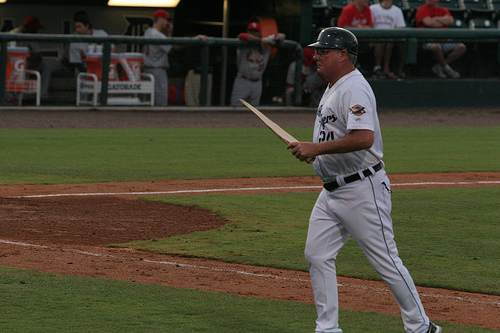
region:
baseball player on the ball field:
[8, 6, 485, 331]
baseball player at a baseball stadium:
[5, 5, 499, 317]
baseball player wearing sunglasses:
[237, 20, 444, 308]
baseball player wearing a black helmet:
[247, 13, 456, 325]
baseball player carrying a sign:
[226, 21, 450, 331]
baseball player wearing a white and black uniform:
[217, 15, 429, 327]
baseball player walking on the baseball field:
[217, 25, 444, 325]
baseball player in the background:
[3, 8, 485, 101]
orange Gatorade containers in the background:
[9, 9, 205, 125]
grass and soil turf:
[13, 114, 488, 325]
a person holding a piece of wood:
[243, 114, 396, 171]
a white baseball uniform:
[314, 67, 427, 331]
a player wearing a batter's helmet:
[305, 22, 362, 53]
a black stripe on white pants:
[362, 187, 389, 247]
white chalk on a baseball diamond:
[88, 185, 122, 200]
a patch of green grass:
[144, 192, 246, 212]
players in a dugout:
[136, 7, 277, 85]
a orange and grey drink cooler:
[6, 44, 31, 92]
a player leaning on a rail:
[231, 21, 288, 76]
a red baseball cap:
[150, 6, 175, 21]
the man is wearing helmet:
[301, 26, 374, 61]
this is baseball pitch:
[4, 131, 246, 328]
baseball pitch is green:
[3, 282, 182, 328]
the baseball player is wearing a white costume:
[317, 71, 409, 331]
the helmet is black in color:
[313, 24, 356, 49]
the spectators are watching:
[0, 15, 454, 92]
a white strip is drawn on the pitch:
[16, 186, 314, 196]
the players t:
[299, 178, 394, 332]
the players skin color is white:
[346, 133, 365, 142]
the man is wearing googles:
[313, 48, 330, 54]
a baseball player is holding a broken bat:
[229, 28, 466, 331]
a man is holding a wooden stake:
[237, 20, 472, 330]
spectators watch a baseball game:
[11, 12, 319, 105]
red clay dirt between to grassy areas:
[131, 248, 296, 304]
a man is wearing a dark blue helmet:
[303, 21, 386, 96]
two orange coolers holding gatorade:
[78, 49, 172, 106]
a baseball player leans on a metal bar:
[229, 17, 289, 102]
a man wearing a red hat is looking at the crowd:
[131, 10, 197, 97]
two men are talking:
[5, 9, 117, 71]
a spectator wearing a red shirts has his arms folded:
[409, 0, 484, 72]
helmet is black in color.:
[308, 28, 381, 73]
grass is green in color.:
[83, 131, 166, 164]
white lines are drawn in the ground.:
[61, 207, 221, 317]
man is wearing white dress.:
[309, 81, 424, 326]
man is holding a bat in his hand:
[240, 81, 317, 181]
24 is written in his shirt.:
[313, 128, 344, 149]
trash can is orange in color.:
[11, 52, 36, 98]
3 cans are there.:
[8, 46, 165, 98]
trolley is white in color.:
[73, 71, 193, 106]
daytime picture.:
[38, 30, 444, 313]